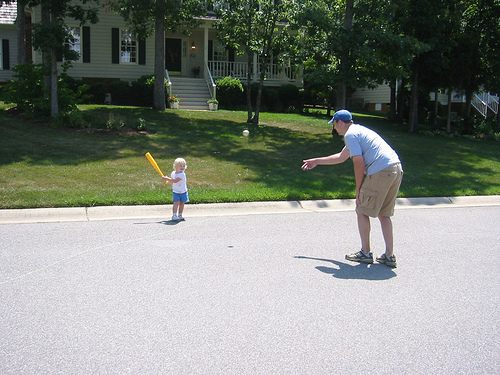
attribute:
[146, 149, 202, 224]
girl — little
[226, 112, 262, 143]
ball — airborne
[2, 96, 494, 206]
grass — green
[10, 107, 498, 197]
grass — green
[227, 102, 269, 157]
ball — airborne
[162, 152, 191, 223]
girl — little, yellow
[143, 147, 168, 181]
bat — plastic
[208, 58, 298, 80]
railing — white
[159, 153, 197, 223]
kid — little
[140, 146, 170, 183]
bat — yellow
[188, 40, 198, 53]
porch light — on